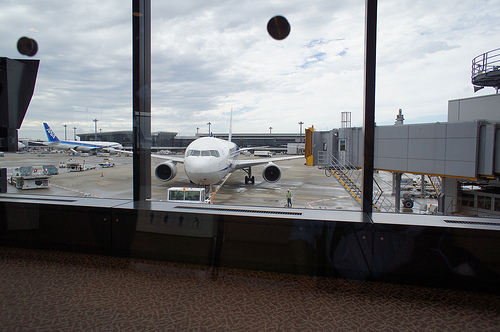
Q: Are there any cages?
A: No, there are no cages.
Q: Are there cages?
A: No, there are no cages.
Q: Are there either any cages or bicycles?
A: No, there are no cages or bicycles.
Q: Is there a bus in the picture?
A: No, there are no buses.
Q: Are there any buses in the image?
A: No, there are no buses.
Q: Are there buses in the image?
A: No, there are no buses.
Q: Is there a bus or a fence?
A: No, there are no buses or fences.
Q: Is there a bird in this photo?
A: No, there are no birds.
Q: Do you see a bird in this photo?
A: No, there are no birds.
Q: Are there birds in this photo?
A: No, there are no birds.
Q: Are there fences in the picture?
A: No, there are no fences.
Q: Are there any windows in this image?
A: Yes, there is a window.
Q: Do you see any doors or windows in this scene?
A: Yes, there is a window.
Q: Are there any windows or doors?
A: Yes, there is a window.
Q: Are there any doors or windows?
A: Yes, there is a window.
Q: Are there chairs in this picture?
A: No, there are no chairs.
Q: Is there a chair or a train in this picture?
A: No, there are no chairs or trains.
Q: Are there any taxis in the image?
A: Yes, there are taxis.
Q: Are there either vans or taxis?
A: Yes, there are taxis.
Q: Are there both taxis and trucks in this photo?
A: Yes, there are both taxis and a truck.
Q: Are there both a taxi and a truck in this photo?
A: Yes, there are both a taxi and a truck.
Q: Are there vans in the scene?
A: No, there are no vans.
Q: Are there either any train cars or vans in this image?
A: No, there are no vans or train cars.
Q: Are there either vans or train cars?
A: No, there are no vans or train cars.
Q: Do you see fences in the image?
A: No, there are no fences.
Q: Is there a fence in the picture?
A: No, there are no fences.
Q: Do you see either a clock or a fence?
A: No, there are no fences or clocks.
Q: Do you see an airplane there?
A: Yes, there is an airplane.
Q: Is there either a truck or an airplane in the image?
A: Yes, there is an airplane.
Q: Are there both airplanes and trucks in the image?
A: Yes, there are both an airplane and a truck.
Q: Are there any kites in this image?
A: No, there are no kites.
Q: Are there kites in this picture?
A: No, there are no kites.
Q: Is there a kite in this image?
A: No, there are no kites.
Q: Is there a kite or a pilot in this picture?
A: No, there are no kites or pilots.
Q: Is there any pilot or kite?
A: No, there are no kites or pilots.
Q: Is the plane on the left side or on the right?
A: The plane is on the left of the image.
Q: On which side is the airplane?
A: The airplane is on the left of the image.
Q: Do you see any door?
A: Yes, there is a door.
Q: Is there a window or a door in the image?
A: Yes, there is a door.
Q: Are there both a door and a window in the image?
A: Yes, there are both a door and a window.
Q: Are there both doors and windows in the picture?
A: Yes, there are both a door and a window.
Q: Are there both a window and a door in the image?
A: Yes, there are both a door and a window.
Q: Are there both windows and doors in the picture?
A: Yes, there are both a door and a window.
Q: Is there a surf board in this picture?
A: No, there are no surfboards.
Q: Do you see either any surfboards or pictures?
A: No, there are no surfboards or pictures.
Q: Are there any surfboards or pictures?
A: No, there are no surfboards or pictures.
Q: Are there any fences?
A: No, there are no fences.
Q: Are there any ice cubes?
A: No, there are no ice cubes.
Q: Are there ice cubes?
A: No, there are no ice cubes.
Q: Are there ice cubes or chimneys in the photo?
A: No, there are no ice cubes or chimneys.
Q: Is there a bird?
A: No, there are no birds.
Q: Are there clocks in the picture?
A: No, there are no clocks.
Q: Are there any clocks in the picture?
A: No, there are no clocks.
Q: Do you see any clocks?
A: No, there are no clocks.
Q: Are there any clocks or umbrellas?
A: No, there are no clocks or umbrellas.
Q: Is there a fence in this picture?
A: No, there are no fences.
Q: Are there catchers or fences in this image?
A: No, there are no fences or catchers.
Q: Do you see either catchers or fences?
A: No, there are no fences or catchers.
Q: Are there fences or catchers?
A: No, there are no fences or catchers.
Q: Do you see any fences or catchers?
A: No, there are no fences or catchers.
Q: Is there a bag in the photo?
A: No, there are no bags.